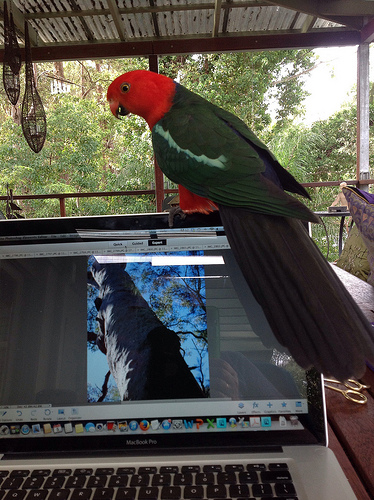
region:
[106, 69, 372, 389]
a blue and green parrot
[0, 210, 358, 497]
an apple laptop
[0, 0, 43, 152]
decorations hanging on the ceiling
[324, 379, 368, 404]
scissors sitting on a table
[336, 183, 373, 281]
pillows on top each other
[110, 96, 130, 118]
the beak of a parrot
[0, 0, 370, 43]
a tin roof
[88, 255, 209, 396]
a picture on the laptop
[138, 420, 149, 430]
firefox the web browser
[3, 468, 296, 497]
keyboard on the laptop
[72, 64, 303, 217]
the bird is sitting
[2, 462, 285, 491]
keyes on the keyboard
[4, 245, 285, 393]
screen on the laptop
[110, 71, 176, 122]
head of the bird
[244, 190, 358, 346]
tail of the bird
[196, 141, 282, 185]
wings of the bird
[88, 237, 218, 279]
reflection on the screen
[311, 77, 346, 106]
the sky is bright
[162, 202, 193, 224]
feet of the bird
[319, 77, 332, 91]
this is the sky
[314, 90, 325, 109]
the sky is bright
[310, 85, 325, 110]
the sky has clouds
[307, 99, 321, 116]
the clouds are white in color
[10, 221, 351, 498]
this is a laptop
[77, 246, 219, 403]
the screen is on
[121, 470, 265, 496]
the buttons are black in color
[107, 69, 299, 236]
this is a parrot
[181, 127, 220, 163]
the feathers are green in color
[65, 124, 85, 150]
the leaves are green in color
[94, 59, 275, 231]
this is a parrot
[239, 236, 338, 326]
the tail is long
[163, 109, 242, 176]
these are the feathers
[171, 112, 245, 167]
the feathers are green in color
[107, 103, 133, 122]
this is the beak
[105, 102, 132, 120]
the beak is curved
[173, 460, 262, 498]
this is the keyboard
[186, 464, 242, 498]
the buttons are black in color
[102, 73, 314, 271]
this is a bird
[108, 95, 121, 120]
this is the beak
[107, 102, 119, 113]
the beak is red in color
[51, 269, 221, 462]
this is a laptop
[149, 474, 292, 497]
these are the buttons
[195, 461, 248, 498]
the buttons are black in color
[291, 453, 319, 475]
the laptop is white in color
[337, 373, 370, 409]
this is a scissor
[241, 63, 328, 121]
this is a tree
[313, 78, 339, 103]
this is the sky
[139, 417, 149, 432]
orange and blue mozilla symbol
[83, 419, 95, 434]
white and blue messenger symbol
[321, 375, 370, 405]
shiny gold scissor handles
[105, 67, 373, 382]
parrot sitting on laptop screen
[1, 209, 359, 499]
black and grey laptop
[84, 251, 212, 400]
picture of a tree on laptop screen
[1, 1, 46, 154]
brown objects hanging from roof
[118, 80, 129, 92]
yellow and black parrot eye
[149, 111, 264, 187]
green wing with white stripe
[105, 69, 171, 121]
red parrot head with red beak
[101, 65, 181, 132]
red head on bird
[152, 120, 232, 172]
white mark on bird wing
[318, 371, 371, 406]
scissors on table